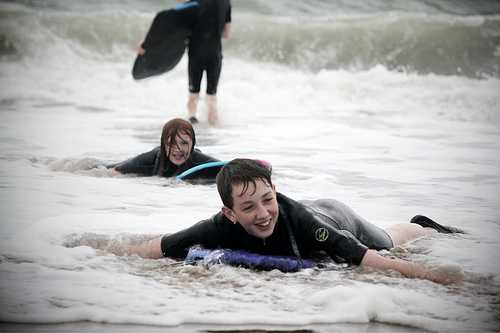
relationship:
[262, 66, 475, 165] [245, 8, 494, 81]
water has waves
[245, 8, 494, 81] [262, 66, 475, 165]
waves are in water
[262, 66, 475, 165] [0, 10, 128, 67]
water has a wave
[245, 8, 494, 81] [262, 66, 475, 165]
waves in water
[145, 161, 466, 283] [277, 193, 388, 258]
boy has on a wet suit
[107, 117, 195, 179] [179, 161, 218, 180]
girl on a surfboard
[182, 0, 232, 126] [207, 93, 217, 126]
person has bare leg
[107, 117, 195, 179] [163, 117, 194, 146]
girl has wet hair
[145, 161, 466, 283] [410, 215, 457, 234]
boy has wet shoes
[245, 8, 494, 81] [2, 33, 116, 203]
waves are in ocean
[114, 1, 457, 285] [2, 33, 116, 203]
kids are in ocean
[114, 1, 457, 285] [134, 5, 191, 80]
kids are on bodyboards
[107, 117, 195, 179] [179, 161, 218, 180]
girl on a bright blue board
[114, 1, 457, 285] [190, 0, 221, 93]
kids are wearing wet suits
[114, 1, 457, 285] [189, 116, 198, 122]
kids are wearing shoes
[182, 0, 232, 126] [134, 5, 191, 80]
person carrying a bodyboards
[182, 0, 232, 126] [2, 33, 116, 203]
person standing in ocean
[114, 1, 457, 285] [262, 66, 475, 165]
kids are in water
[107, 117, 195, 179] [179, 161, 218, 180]
girl on a board